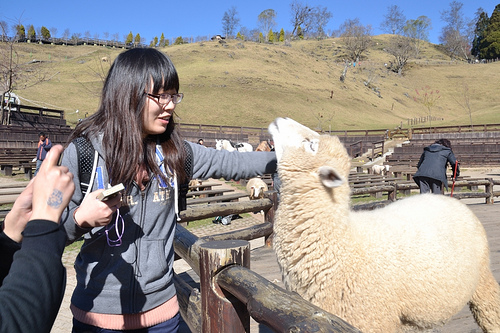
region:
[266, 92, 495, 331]
sheep loves to be petted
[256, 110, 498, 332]
white sheep inside of gate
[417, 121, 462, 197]
woman in black jacket inside of gate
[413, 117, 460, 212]
woman is using a shovel to pick up stuff inside of gate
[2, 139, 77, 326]
person is taking a picture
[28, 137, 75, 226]
person has a stamp on her hand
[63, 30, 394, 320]
woman with a grey coat is petting sheep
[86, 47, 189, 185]
girl with black hair and glasses outside of gate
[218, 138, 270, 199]
group of sheep in background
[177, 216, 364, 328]
wooden gate to keep sheep in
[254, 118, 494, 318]
The sheep is beige.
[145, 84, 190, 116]
Girl is wearing glasses.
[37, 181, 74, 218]
Tattoo on the hand.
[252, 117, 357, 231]
Girl is petting the sheep.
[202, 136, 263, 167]
Horse in the background.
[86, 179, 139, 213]
Girl is holding a phone.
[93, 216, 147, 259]
Earbuds in the pocket.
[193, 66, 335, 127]
The hill is greenish brown.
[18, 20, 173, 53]
Bridge in the background.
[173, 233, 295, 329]
The fence is made of wood.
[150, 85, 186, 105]
glasses on a woman's face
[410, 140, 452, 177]
a dark gray jacket on a person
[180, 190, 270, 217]
a wood rail on a fence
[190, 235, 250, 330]
a wooden fence post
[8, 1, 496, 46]
blue sky above a hillside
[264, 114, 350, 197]
the lifted head of a sheep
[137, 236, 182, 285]
a pocket on a jacket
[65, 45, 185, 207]
black hair on a woman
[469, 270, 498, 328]
the leg of a sheep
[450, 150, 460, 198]
a red broom handle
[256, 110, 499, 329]
a sheep lifting its head up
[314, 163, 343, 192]
the ear of a sheep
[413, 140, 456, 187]
a dark jacket on a person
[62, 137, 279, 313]
a grey sweatshirt on a woman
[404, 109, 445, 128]
a fence on a hillside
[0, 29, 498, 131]
a hill above a sheep pen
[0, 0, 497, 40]
a blue sky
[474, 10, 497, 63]
a pine tree on a hill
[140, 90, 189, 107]
glasses over the woman's eyes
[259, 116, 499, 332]
white and tan sheep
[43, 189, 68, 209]
tattoo on the back of someones hand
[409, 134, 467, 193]
person in a gray coat sweeping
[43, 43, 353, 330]
a woman petting a sheep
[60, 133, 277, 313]
gray zip hoodie on the woman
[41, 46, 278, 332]
woman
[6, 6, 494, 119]
large brown hill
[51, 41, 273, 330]
woman with dark colored hair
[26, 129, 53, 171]
a person in the distance